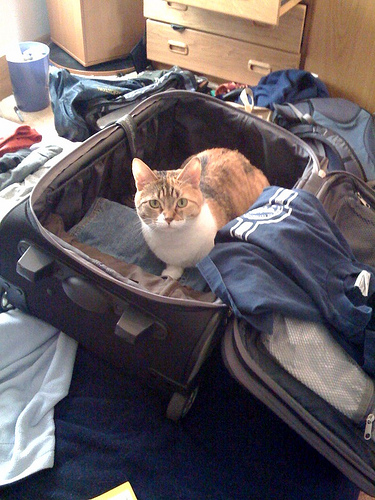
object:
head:
[130, 155, 202, 231]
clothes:
[167, 22, 190, 33]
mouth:
[160, 222, 178, 232]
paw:
[158, 266, 184, 280]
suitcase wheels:
[166, 388, 198, 423]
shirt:
[195, 184, 375, 376]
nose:
[160, 207, 175, 225]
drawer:
[145, 18, 302, 90]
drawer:
[142, 1, 307, 54]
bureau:
[0, 0, 375, 497]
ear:
[177, 157, 201, 191]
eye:
[174, 195, 189, 211]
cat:
[131, 146, 271, 279]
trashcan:
[5, 41, 51, 114]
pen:
[14, 105, 26, 123]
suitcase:
[0, 86, 375, 499]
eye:
[148, 199, 162, 212]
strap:
[277, 122, 364, 183]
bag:
[267, 95, 374, 185]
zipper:
[361, 409, 373, 441]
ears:
[132, 156, 159, 188]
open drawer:
[161, 0, 301, 25]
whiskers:
[133, 210, 159, 237]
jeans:
[66, 194, 206, 295]